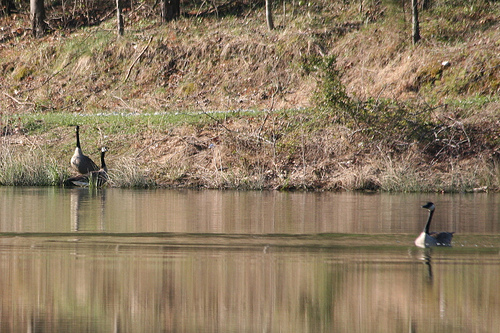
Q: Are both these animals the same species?
A: No, they are geese and birds.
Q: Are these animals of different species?
A: Yes, they are geese and birds.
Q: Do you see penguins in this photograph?
A: No, there are no penguins.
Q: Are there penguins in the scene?
A: No, there are no penguins.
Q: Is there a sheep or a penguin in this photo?
A: No, there are no penguins or sheep.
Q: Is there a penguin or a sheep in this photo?
A: No, there are no penguins or sheep.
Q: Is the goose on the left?
A: Yes, the goose is on the left of the image.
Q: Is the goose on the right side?
A: No, the goose is on the left of the image.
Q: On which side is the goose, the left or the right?
A: The goose is on the left of the image.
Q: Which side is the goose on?
A: The goose is on the left of the image.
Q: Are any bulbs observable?
A: No, there are no bulbs.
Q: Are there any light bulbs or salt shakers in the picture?
A: No, there are no light bulbs or salt shakers.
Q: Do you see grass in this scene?
A: Yes, there is grass.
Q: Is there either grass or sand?
A: Yes, there is grass.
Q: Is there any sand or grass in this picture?
A: Yes, there is grass.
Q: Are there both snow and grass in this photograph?
A: No, there is grass but no snow.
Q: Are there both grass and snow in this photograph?
A: No, there is grass but no snow.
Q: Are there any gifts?
A: No, there are no gifts.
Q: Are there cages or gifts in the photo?
A: No, there are no gifts or cages.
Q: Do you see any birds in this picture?
A: Yes, there is a bird.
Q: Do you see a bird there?
A: Yes, there is a bird.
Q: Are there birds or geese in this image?
A: Yes, there is a bird.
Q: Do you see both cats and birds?
A: No, there is a bird but no cats.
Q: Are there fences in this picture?
A: No, there are no fences.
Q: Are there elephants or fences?
A: No, there are no fences or elephants.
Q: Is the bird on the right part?
A: Yes, the bird is on the right of the image.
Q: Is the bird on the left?
A: No, the bird is on the right of the image.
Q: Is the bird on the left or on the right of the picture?
A: The bird is on the right of the image.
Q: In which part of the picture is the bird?
A: The bird is on the right of the image.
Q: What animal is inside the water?
A: The bird is inside the water.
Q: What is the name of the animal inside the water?
A: The animal is a bird.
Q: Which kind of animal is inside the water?
A: The animal is a bird.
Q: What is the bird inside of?
A: The bird is inside the water.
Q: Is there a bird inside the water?
A: Yes, there is a bird inside the water.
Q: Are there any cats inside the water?
A: No, there is a bird inside the water.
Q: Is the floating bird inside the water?
A: Yes, the bird is inside the water.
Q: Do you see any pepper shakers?
A: No, there are no pepper shakers.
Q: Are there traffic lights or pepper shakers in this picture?
A: No, there are no pepper shakers or traffic lights.